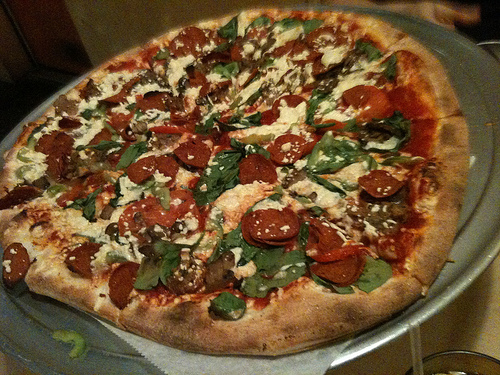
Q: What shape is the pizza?
A: Round.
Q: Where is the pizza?
A: On the tray.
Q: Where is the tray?
A: On the table.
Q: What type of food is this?
A: Pizza.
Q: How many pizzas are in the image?
A: One.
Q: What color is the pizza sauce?
A: Red.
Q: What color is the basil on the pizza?
A: Green.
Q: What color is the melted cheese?
A: White.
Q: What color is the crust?
A: Brown.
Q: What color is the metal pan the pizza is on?
A: Silver.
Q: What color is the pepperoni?
A: Brown.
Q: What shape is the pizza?
A: Round.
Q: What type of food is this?
A: Pizza.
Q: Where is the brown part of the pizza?
A: The crust.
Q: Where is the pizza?
A: On a tray.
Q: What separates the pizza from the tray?
A: Paper.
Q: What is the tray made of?
A: Metal.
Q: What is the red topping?
A: Pepperoni.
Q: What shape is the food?
A: Circle.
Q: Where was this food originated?
A: Italy.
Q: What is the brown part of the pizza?
A: Crust.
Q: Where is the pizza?
A: Pizza pan.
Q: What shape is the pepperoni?
A: Circle.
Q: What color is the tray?
A: Silver.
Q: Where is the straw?
A: In the cup.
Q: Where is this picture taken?
A: In a restaurant.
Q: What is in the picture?
A: A pizza.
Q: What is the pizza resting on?
A: A pan.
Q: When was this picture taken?
A: After the pizza baked.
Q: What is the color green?
A: Fresh basil.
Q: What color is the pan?
A: Silver.